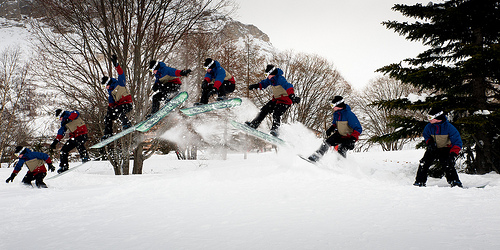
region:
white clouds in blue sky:
[274, 3, 370, 56]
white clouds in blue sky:
[255, 10, 307, 43]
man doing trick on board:
[405, 101, 478, 214]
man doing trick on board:
[320, 91, 357, 151]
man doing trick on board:
[245, 52, 286, 152]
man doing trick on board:
[192, 37, 247, 107]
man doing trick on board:
[135, 63, 168, 100]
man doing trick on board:
[85, 75, 157, 156]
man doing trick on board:
[46, 101, 83, 142]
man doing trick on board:
[4, 118, 61, 195]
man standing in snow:
[392, 100, 478, 197]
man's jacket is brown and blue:
[420, 120, 471, 160]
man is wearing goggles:
[418, 108, 450, 125]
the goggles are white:
[423, 110, 449, 123]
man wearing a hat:
[420, 93, 441, 118]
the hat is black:
[425, 103, 446, 119]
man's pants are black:
[416, 147, 461, 187]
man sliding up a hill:
[297, 90, 368, 177]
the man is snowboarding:
[237, 50, 310, 146]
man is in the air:
[88, 51, 145, 154]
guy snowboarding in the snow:
[409, 104, 480, 204]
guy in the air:
[190, 48, 245, 119]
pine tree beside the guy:
[369, 3, 498, 105]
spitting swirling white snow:
[172, 120, 234, 157]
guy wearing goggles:
[8, 142, 50, 189]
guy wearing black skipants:
[411, 101, 461, 198]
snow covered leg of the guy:
[298, 137, 326, 169]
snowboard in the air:
[172, 96, 259, 121]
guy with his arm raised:
[90, 48, 133, 144]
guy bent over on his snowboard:
[197, 55, 233, 115]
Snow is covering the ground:
[2, 159, 498, 249]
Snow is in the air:
[163, 98, 319, 177]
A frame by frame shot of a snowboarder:
[1, 49, 471, 199]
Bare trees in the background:
[3, 2, 423, 151]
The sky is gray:
[2, 4, 426, 110]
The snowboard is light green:
[83, 85, 290, 167]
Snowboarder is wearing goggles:
[420, 105, 450, 127]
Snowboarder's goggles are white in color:
[414, 100, 448, 128]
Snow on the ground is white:
[6, 153, 498, 246]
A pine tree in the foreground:
[364, 3, 498, 178]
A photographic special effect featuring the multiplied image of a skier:
[10, 60, 470, 203]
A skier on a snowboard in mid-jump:
[247, 63, 292, 150]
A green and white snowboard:
[132, 97, 189, 132]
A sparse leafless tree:
[71, 3, 181, 53]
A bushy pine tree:
[388, 3, 495, 108]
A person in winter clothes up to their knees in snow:
[4, 140, 61, 192]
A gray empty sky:
[307, 10, 380, 52]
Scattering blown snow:
[163, 116, 243, 159]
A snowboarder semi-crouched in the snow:
[411, 99, 478, 203]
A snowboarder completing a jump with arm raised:
[97, 58, 134, 140]